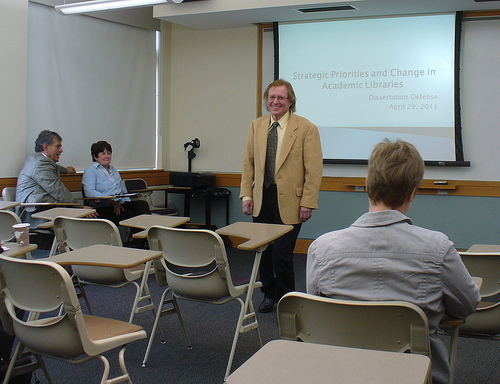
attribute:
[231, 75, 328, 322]
man — wearing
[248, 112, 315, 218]
jacket — tan, suit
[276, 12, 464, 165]
screen — black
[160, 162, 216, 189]
projector — black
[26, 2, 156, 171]
shade — white, drawn, across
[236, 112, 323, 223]
jacket — khaki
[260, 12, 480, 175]
screen — hanging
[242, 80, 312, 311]
person — standing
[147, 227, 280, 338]
chair — empty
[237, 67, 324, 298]
adult male — smiling, white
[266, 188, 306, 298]
pants — black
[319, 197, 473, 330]
jacket — grey